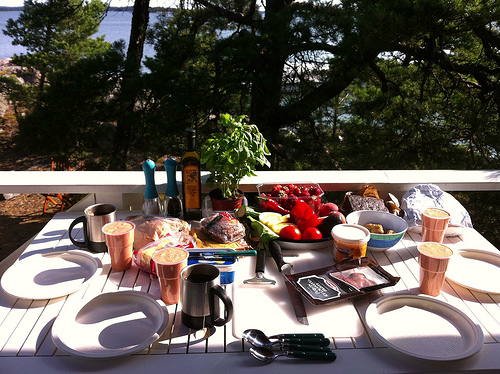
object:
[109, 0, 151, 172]
trees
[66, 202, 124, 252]
mug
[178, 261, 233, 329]
mug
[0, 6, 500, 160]
water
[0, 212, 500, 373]
picnic table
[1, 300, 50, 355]
boards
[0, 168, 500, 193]
railing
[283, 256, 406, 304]
menu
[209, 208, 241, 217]
case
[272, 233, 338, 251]
bowl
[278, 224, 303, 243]
vegetables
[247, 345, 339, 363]
spoon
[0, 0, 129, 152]
trees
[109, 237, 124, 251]
glass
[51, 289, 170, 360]
plate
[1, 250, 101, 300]
plate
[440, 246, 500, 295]
plate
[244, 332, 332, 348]
spoons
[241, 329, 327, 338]
spoons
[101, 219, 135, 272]
cup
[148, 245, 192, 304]
cup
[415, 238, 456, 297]
cup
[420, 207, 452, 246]
cup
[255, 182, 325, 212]
bowl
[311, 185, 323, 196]
berry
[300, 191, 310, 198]
berry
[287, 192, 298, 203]
berry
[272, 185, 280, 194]
berry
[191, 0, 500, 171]
tree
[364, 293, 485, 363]
bowl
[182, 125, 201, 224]
bottle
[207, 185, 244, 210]
vase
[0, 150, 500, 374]
porch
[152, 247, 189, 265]
drink